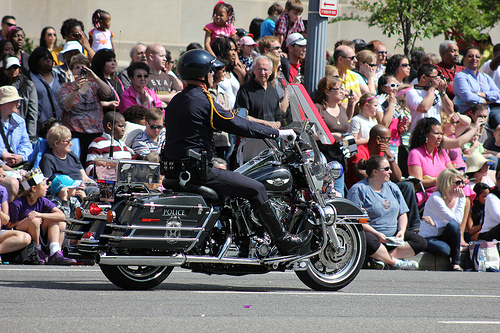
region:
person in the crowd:
[410, 115, 457, 175]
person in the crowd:
[41, 125, 76, 177]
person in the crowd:
[363, 160, 404, 266]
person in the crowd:
[13, 171, 73, 256]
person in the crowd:
[428, 160, 462, 221]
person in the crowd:
[311, 77, 356, 129]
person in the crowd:
[240, 54, 285, 119]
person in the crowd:
[63, 58, 115, 128]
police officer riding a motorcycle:
[75, 38, 380, 288]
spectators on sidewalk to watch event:
[14, 10, 480, 253]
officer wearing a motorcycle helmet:
[167, 43, 234, 105]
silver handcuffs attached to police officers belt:
[171, 161, 195, 195]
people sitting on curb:
[362, 177, 495, 259]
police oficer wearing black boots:
[250, 190, 325, 261]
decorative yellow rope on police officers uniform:
[192, 79, 235, 131]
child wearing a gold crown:
[9, 161, 65, 255]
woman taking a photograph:
[62, 55, 119, 130]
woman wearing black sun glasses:
[117, 60, 158, 107]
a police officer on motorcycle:
[60, 49, 368, 291]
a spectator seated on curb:
[349, 155, 424, 268]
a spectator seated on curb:
[418, 168, 470, 270]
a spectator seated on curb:
[12, 170, 78, 266]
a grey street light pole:
[302, 0, 328, 90]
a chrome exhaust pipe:
[92, 252, 184, 267]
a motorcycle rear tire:
[97, 263, 174, 288]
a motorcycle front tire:
[291, 218, 366, 292]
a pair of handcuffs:
[177, 169, 189, 186]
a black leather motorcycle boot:
[253, 200, 313, 255]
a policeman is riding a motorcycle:
[62, 46, 375, 296]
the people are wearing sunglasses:
[342, 40, 413, 92]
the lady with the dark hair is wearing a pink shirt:
[406, 114, 452, 180]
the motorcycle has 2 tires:
[89, 188, 374, 300]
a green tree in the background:
[334, 1, 498, 42]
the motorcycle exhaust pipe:
[88, 247, 275, 272]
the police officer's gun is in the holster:
[184, 145, 217, 185]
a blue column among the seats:
[302, 13, 331, 100]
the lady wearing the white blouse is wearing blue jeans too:
[426, 218, 470, 272]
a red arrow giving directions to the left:
[310, 1, 350, 24]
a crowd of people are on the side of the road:
[6, 9, 498, 315]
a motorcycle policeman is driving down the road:
[56, 46, 372, 293]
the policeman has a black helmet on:
[175, 45, 221, 89]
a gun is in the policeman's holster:
[181, 143, 218, 181]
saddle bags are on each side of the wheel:
[84, 187, 211, 274]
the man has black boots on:
[218, 190, 310, 259]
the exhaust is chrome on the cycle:
[91, 245, 208, 272]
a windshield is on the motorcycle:
[276, 75, 342, 155]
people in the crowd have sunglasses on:
[334, 40, 435, 98]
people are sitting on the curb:
[7, 153, 498, 275]